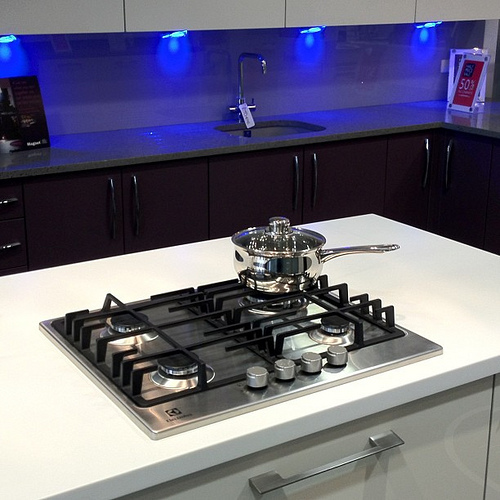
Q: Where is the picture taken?
A: Kitchen.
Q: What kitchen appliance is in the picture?
A: Stove.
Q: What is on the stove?
A: Saucepan.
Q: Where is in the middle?
A: Kitchen island.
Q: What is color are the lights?
A: Blue.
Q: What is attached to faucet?
A: Tag.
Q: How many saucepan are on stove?
A: One.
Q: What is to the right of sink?
A: Information tag.